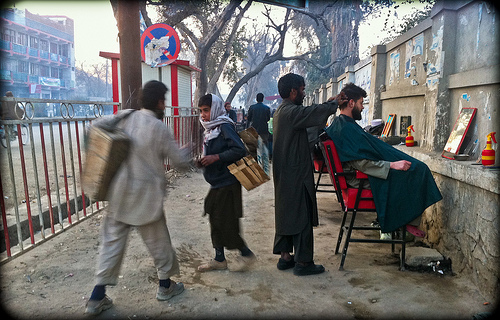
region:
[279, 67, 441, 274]
a man getting a haircut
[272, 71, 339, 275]
a barber on the street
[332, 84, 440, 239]
man in a green smock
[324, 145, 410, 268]
red barber chair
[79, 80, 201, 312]
man in light gray carrying a crate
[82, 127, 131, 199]
wooden crate in man's arms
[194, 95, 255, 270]
woman with gray head scarf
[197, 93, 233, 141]
gray head scarf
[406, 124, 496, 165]
two red and yellow squirt bottles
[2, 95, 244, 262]
red and white metal fence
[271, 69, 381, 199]
Man giving haircut outside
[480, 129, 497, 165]
Spray bottle with red and yellow stripes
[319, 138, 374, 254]
Red and black barber's chair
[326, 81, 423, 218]
Man wearing blue barber's cape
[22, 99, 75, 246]
Red and white rail fence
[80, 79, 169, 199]
Man carrying wooden basket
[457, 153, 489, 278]
Stone wall with ledge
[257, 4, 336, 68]
Tree branches with no leaves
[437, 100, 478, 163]
Mirror leaning against stone wall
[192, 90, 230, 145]
Person wearing head wrap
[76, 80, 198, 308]
Man wearing gray pants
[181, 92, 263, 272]
Woman wearing black top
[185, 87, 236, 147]
Gray scarf on woman's head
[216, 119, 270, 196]
Brown purse on woman's shoulder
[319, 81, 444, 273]
Man sitting in a red chair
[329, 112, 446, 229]
Blue smock covering man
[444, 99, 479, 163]
Mirror leaning against wall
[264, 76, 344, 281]
Man wearing all black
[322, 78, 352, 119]
clippers in man's hand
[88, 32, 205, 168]
Red and white shed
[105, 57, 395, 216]
people in the photo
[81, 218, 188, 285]
legs of the person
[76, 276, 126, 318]
shoe on the person's foot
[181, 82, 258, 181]
person with something around head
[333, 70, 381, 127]
head of a man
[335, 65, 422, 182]
man sitting in chair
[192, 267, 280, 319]
ground below the people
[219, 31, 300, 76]
branches of the tree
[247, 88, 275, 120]
man in the background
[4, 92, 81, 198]
fence next to the man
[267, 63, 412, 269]
man getting his hair cut by outdoor barber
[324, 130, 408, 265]
tall chair with red cushions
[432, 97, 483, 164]
mirrow leaning againt wall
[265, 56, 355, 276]
barber cutting hair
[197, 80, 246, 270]
woman with a scarf on her head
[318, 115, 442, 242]
blue blanket covering man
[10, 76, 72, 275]
silver and red iron fence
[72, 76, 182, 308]
man carrying a basket on shoulder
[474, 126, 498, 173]
red and yellow spray bottle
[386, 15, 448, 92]
signs peeling off of wall